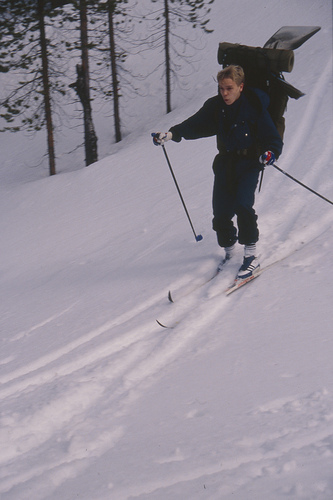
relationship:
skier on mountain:
[161, 63, 283, 278] [5, 0, 330, 498]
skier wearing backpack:
[161, 63, 283, 278] [218, 26, 321, 143]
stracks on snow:
[0, 57, 329, 499] [3, 4, 329, 499]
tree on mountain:
[136, 2, 217, 112] [5, 0, 330, 498]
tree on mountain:
[94, 2, 147, 141] [5, 0, 330, 498]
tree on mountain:
[60, 3, 109, 163] [5, 0, 330, 498]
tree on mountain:
[0, 0, 64, 176] [5, 0, 330, 498]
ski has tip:
[156, 260, 267, 329] [155, 318, 172, 330]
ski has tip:
[167, 258, 219, 305] [166, 288, 178, 303]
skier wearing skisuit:
[161, 63, 283, 278] [171, 94, 284, 244]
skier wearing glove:
[161, 63, 283, 278] [259, 150, 275, 167]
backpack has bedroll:
[218, 26, 321, 143] [217, 42, 294, 73]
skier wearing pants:
[161, 63, 283, 278] [212, 172, 259, 248]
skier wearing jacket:
[161, 63, 283, 278] [172, 89, 281, 158]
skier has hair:
[161, 63, 283, 278] [218, 64, 245, 89]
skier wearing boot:
[161, 63, 283, 278] [237, 255, 261, 280]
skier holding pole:
[161, 63, 283, 278] [266, 162, 332, 206]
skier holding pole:
[161, 63, 283, 278] [160, 145, 204, 242]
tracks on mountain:
[1, 54, 331, 495] [5, 0, 330, 498]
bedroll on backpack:
[217, 42, 294, 73] [218, 26, 321, 143]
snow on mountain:
[3, 4, 329, 499] [5, 0, 330, 498]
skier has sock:
[161, 63, 283, 278] [241, 243, 255, 259]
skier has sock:
[161, 63, 283, 278] [222, 245, 237, 257]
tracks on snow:
[1, 54, 331, 495] [3, 4, 329, 499]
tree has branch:
[0, 0, 64, 176] [3, 76, 40, 102]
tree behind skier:
[136, 2, 217, 112] [161, 63, 283, 278]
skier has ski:
[161, 63, 283, 278] [156, 260, 267, 329]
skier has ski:
[161, 63, 283, 278] [167, 258, 219, 305]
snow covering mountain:
[3, 4, 329, 499] [5, 0, 330, 498]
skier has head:
[161, 63, 283, 278] [218, 67, 246, 104]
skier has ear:
[161, 63, 283, 278] [238, 82, 245, 93]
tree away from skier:
[136, 2, 217, 112] [161, 63, 283, 278]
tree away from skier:
[94, 2, 147, 141] [161, 63, 283, 278]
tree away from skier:
[60, 3, 109, 163] [161, 63, 283, 278]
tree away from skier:
[0, 0, 64, 176] [161, 63, 283, 278]